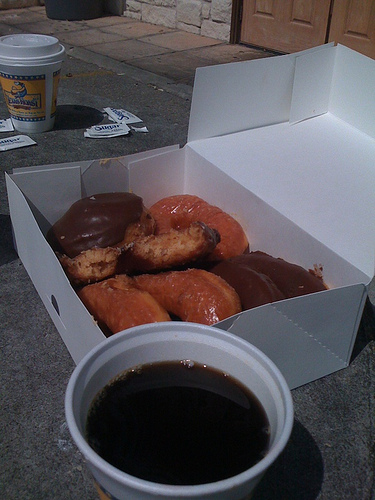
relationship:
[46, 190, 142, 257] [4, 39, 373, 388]
chocolate inside box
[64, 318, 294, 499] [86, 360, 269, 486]
cup of coffee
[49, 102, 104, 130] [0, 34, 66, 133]
shadow of cup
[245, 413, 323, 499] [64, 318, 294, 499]
shadow of cup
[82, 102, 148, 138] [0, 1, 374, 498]
packs on floor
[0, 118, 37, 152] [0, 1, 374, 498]
packs on floor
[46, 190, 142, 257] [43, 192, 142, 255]
chocolate has chocolate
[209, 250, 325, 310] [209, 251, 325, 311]
chocolate has chocolate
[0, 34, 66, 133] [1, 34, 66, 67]
cup has lid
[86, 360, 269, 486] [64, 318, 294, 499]
coffee in cup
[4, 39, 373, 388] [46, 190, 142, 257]
box of chocolate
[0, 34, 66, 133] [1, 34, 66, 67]
cup with lid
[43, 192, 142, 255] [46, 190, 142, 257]
chocolate on chocolate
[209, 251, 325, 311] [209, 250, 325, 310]
chocolate on chocolate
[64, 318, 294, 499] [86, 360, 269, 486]
cup with coffee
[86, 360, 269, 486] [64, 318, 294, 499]
coffee inside cup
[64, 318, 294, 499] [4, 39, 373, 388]
cup before box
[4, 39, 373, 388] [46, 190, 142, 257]
box containing chocolate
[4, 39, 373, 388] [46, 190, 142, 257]
box with chocolate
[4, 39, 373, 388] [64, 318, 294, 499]
box and a cup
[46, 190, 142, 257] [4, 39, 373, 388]
chocolate in a box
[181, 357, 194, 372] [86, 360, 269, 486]
bubble in coffee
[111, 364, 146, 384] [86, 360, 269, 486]
bubble in coffee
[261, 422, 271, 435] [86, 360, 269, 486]
bubble in coffee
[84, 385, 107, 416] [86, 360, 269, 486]
bubble in coffee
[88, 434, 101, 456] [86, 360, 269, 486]
bubble in coffee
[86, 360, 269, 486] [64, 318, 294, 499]
coffee in a cup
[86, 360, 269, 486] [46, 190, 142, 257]
coffee next to chocolate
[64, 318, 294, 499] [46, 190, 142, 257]
cup next to chocolate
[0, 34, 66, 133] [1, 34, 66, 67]
cup with a lid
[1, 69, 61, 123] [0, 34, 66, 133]
design on cup